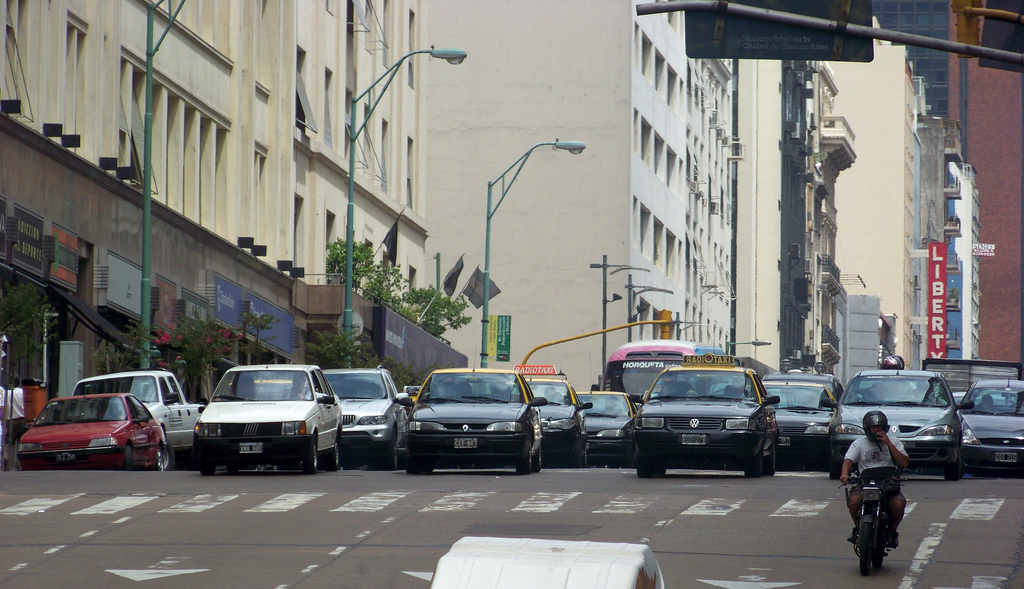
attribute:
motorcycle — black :
[828, 463, 904, 574]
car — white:
[194, 358, 347, 473]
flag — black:
[379, 216, 400, 267]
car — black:
[630, 349, 779, 479]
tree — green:
[153, 313, 239, 403]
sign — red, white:
[929, 243, 948, 362]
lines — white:
[1, 471, 994, 536]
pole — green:
[462, 154, 523, 355]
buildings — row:
[4, 0, 981, 402]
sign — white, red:
[928, 238, 952, 369]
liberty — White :
[920, 233, 972, 366]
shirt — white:
[837, 431, 915, 481]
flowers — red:
[157, 329, 177, 356]